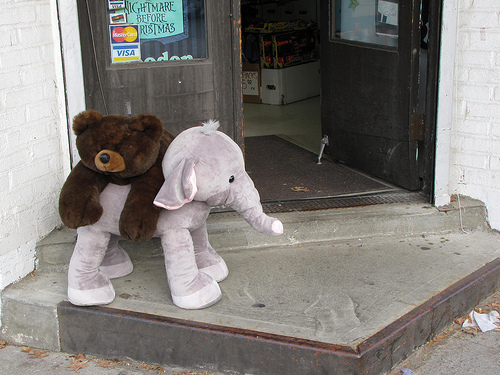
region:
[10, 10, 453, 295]
stuffed animals on the steps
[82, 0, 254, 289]
movie advertisement above the bears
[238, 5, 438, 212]
this is some kind of store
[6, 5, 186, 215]
the wall is brick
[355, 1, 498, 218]
brick white walls near the door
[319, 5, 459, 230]
the door is old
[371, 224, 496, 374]
trash by the steps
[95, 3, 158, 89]
credit card logos on display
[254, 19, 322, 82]
this is some kind of product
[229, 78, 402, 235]
a dirty mat on the ground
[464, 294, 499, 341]
piece of scrap paper with dead leaves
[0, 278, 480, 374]
a concrete step with metal edge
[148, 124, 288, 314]
a faded purple elephant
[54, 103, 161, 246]
a brown teddy bear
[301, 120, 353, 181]
a metal door stop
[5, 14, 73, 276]
brick painted white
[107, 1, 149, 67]
posting of credit cards accepted by store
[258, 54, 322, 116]
white box with handles in the sides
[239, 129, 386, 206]
a carpet type door mat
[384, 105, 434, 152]
Rusted door hinge on wooden door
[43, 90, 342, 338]
Stuffed animals on the stoop.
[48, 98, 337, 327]
Stuffed elephant with a stuffed bear.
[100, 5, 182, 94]
Credit card logos on the window.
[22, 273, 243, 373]
Step in front of the door.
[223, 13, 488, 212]
Door that is open.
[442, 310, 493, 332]
Trash by the stoop.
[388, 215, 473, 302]
Stains on the stoop.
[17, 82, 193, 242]
Bear on the elephant's back.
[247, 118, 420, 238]
Carpet on the floor.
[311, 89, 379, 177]
Door jamb.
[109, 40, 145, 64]
a blue and white Visa sign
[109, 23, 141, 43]
a MasterCard sign on the door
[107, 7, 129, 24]
a Discover card sign on the door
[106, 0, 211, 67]
a glass window on the door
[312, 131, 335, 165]
a metal door stop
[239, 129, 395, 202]
a floor mat on the floor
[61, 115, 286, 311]
a stuffed animal elephant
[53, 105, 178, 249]
a large brown teddy bear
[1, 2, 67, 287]
a white brick wall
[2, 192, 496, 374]
cement door steps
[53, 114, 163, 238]
a dark brown plush teddy bear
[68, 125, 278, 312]
a standing grey plush elephant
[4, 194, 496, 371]
a diagonal step entrance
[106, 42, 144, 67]
Visa credit card acceptance sign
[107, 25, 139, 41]
MasterCard credit card acceptance sign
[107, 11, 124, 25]
Discover credit card acceptance sign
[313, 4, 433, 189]
a propped open door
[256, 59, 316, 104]
a white cardboard box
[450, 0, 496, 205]
white painted brick wall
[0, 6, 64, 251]
white painted brick wall